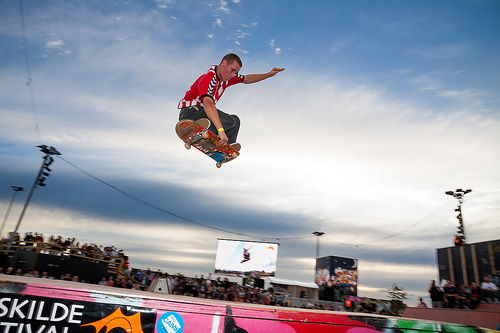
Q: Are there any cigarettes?
A: No, there are no cigarettes.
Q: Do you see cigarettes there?
A: No, there are no cigarettes.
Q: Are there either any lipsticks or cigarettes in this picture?
A: No, there are no cigarettes or lipsticks.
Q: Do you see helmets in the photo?
A: No, there are no helmets.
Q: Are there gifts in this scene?
A: No, there are no gifts.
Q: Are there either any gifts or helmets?
A: No, there are no gifts or helmets.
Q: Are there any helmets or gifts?
A: No, there are no gifts or helmets.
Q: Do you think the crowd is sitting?
A: Yes, the crowd is sitting.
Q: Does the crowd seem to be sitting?
A: Yes, the crowd is sitting.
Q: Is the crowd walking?
A: No, the crowd is sitting.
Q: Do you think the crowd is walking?
A: No, the crowd is sitting.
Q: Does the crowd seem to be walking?
A: No, the crowd is sitting.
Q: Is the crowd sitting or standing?
A: The crowd is sitting.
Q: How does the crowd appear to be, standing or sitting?
A: The crowd is sitting.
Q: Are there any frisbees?
A: No, there are no frisbees.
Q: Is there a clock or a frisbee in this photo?
A: No, there are no frisbees or clocks.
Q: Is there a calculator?
A: No, there are no calculators.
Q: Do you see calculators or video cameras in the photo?
A: No, there are no calculators or video cameras.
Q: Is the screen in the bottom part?
A: Yes, the screen is in the bottom of the image.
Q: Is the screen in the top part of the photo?
A: No, the screen is in the bottom of the image.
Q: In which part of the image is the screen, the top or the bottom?
A: The screen is in the bottom of the image.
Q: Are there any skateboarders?
A: Yes, there is a skateboarder.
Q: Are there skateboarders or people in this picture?
A: Yes, there is a skateboarder.